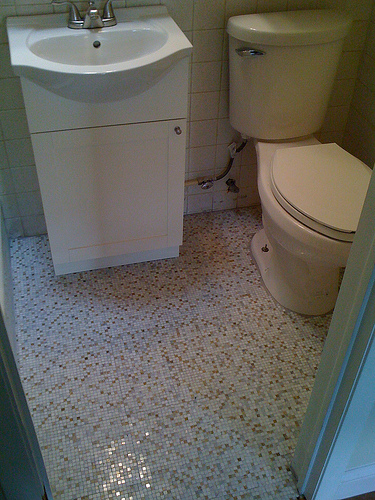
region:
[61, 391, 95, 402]
Small tiles on a bathroom floor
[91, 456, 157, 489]
Light reflected off bathroom tiles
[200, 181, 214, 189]
An oval water valve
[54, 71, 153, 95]
The curved edge of a white sink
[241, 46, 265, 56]
The handle on a toilet tank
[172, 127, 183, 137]
The round sliver knob on a bathroom cabinet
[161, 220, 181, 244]
Raised edge on a cabinet door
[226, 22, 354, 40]
Beige tank lid on a toilet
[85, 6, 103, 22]
Sliver metal faucet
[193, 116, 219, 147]
Square tiles on a bathroom wall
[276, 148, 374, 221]
toilet seat that is closed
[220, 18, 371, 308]
white toilet in the bathroom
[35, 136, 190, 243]
cabinet that is painted white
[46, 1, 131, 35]
silver faucet of sink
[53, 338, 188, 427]
colorful tile on the floor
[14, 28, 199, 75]
white sink attached to wall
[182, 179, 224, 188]
yellow hose attached to toilet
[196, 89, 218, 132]
white tiles on the wall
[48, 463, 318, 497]
entranceway of the bathroom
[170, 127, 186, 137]
silver knob on the cabinet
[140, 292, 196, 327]
tile on the floor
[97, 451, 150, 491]
light on the floor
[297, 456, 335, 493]
side of the wall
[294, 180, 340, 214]
lid of the toilet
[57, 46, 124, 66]
lip of the sink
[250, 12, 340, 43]
tank of the toilet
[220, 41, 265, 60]
handle of the toilet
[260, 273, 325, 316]
bottom of the toilet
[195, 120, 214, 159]
tile on the wall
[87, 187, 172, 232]
door of the cabinet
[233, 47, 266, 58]
a silver flush handle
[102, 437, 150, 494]
light reflection on the tile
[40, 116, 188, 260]
the cabinet door is closed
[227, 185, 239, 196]
water control valve on the wall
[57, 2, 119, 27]
metal sink faucet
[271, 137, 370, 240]
the white toilet seat is down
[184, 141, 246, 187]
a plumbing pipe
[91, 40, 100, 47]
round drain in the sink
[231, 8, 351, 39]
toilet tank lid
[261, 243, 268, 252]
a screw to secure toilet to the ground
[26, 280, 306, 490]
tile on the bathroom floor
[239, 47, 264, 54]
a handle on the toilet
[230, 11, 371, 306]
a white toilet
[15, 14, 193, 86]
a white sink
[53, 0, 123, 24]
a faucet on the sink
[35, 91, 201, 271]
a white cabinet under the sink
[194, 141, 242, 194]
a pipe going to the toilet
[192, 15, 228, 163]
white tile behind the toilet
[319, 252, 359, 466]
the doorway of a bathroom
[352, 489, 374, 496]
floor outside the bathroom